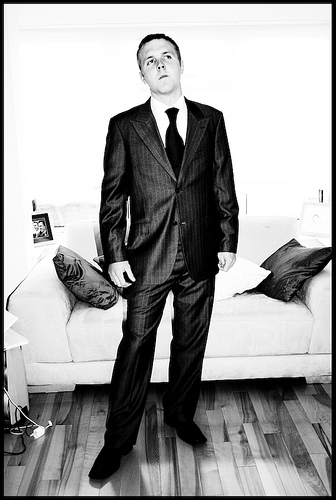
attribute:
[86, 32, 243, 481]
man — young, standing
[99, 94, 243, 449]
suit — dark, black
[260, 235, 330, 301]
pillow — dark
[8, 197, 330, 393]
couch — light, white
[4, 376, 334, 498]
floor — wooden, brown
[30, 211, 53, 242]
picture frame — small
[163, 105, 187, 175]
tie — black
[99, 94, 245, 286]
jacket — striped, dark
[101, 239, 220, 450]
pants — black, striped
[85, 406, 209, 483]
shoes — dark, black